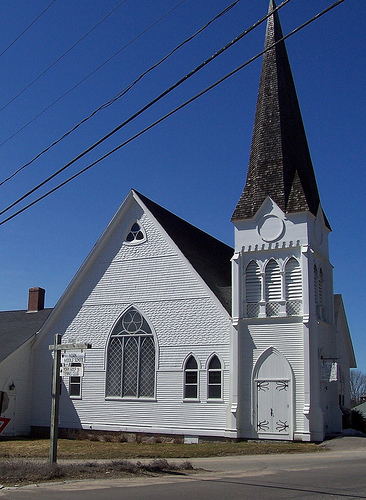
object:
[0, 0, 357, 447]
church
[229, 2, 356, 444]
steeple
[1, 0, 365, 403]
sky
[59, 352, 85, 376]
sign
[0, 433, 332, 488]
grass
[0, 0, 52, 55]
power lines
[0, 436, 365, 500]
road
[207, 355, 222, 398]
windows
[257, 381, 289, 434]
door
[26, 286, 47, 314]
chimney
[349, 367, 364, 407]
tree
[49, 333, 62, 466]
post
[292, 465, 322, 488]
part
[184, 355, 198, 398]
window